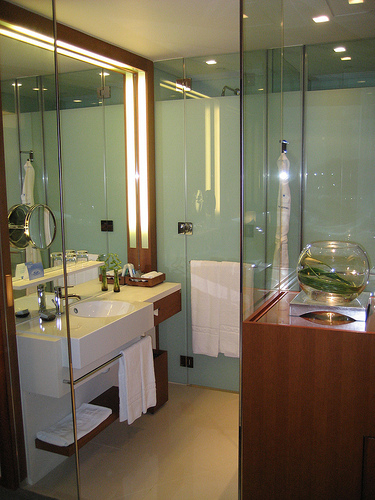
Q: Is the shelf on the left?
A: Yes, the shelf is on the left of the image.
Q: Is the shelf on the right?
A: No, the shelf is on the left of the image.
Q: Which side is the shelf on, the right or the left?
A: The shelf is on the left of the image.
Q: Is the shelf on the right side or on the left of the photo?
A: The shelf is on the left of the image.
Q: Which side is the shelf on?
A: The shelf is on the left of the image.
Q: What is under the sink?
A: The shelf is under the sink.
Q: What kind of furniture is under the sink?
A: The piece of furniture is a shelf.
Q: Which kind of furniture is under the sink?
A: The piece of furniture is a shelf.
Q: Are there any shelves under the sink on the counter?
A: Yes, there is a shelf under the sink.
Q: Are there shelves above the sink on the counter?
A: No, the shelf is under the sink.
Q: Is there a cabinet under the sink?
A: No, there is a shelf under the sink.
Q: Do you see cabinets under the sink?
A: No, there is a shelf under the sink.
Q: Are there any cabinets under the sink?
A: No, there is a shelf under the sink.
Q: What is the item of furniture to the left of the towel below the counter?
A: The piece of furniture is a shelf.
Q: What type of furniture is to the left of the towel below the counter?
A: The piece of furniture is a shelf.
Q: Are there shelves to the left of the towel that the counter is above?
A: Yes, there is a shelf to the left of the towel.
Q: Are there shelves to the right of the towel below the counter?
A: No, the shelf is to the left of the towel.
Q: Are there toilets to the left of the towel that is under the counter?
A: No, there is a shelf to the left of the towel.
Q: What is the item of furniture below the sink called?
A: The piece of furniture is a shelf.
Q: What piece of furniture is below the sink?
A: The piece of furniture is a shelf.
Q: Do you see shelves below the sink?
A: Yes, there is a shelf below the sink.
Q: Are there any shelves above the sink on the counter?
A: No, the shelf is below the sink.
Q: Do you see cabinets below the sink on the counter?
A: No, there is a shelf below the sink.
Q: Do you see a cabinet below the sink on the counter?
A: No, there is a shelf below the sink.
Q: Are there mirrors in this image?
A: Yes, there is a mirror.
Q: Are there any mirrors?
A: Yes, there is a mirror.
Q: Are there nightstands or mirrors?
A: Yes, there is a mirror.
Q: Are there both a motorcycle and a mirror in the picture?
A: No, there is a mirror but no motorcycles.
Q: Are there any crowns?
A: No, there are no crowns.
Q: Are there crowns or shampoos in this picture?
A: No, there are no crowns or shampoos.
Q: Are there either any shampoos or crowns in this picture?
A: No, there are no crowns or shampoos.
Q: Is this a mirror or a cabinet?
A: This is a mirror.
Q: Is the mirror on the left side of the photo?
A: Yes, the mirror is on the left of the image.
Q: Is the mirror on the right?
A: No, the mirror is on the left of the image.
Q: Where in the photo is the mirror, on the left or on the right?
A: The mirror is on the left of the image.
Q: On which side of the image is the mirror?
A: The mirror is on the left of the image.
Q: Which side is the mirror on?
A: The mirror is on the left of the image.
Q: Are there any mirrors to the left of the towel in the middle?
A: Yes, there is a mirror to the left of the towel.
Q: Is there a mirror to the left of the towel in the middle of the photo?
A: Yes, there is a mirror to the left of the towel.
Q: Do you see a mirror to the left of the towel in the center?
A: Yes, there is a mirror to the left of the towel.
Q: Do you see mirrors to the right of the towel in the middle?
A: No, the mirror is to the left of the towel.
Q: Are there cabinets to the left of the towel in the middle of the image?
A: No, there is a mirror to the left of the towel.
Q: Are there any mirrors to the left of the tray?
A: Yes, there is a mirror to the left of the tray.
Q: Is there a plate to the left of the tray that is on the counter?
A: No, there is a mirror to the left of the tray.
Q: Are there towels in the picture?
A: Yes, there is a towel.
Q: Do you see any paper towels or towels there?
A: Yes, there is a towel.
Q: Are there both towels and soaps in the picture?
A: No, there is a towel but no soaps.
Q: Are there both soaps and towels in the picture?
A: No, there is a towel but no soaps.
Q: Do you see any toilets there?
A: No, there are no toilets.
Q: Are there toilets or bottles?
A: No, there are no toilets or bottles.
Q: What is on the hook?
A: The towel is on the hook.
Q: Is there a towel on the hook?
A: Yes, there is a towel on the hook.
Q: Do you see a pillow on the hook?
A: No, there is a towel on the hook.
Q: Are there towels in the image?
A: Yes, there is a towel.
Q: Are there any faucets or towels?
A: Yes, there is a towel.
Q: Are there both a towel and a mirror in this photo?
A: Yes, there are both a towel and a mirror.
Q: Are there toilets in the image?
A: No, there are no toilets.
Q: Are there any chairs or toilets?
A: No, there are no toilets or chairs.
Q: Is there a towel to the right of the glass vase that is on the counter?
A: Yes, there is a towel to the right of the vase.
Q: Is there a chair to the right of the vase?
A: No, there is a towel to the right of the vase.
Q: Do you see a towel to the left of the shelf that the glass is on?
A: No, the towel is to the right of the shelf.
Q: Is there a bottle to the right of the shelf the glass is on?
A: No, there is a towel to the right of the shelf.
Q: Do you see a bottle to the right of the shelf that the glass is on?
A: No, there is a towel to the right of the shelf.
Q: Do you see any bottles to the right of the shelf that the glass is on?
A: No, there is a towel to the right of the shelf.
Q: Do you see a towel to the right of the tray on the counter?
A: Yes, there is a towel to the right of the tray.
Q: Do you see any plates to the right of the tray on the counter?
A: No, there is a towel to the right of the tray.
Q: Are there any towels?
A: Yes, there is a towel.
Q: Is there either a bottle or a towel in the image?
A: Yes, there is a towel.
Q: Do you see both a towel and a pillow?
A: No, there is a towel but no pillows.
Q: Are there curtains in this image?
A: No, there are no curtains.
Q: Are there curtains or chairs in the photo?
A: No, there are no curtains or chairs.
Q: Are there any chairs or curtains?
A: No, there are no curtains or chairs.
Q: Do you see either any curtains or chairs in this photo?
A: No, there are no curtains or chairs.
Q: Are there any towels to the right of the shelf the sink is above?
A: Yes, there is a towel to the right of the shelf.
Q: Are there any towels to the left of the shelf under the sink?
A: No, the towel is to the right of the shelf.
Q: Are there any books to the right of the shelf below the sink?
A: No, there is a towel to the right of the shelf.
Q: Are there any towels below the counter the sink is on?
A: Yes, there is a towel below the counter.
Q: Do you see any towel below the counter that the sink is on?
A: Yes, there is a towel below the counter.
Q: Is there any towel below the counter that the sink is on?
A: Yes, there is a towel below the counter.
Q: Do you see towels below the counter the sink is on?
A: Yes, there is a towel below the counter.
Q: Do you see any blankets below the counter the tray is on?
A: No, there is a towel below the counter.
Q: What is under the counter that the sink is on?
A: The towel is under the counter.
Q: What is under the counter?
A: The towel is under the counter.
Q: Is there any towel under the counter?
A: Yes, there is a towel under the counter.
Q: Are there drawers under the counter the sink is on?
A: No, there is a towel under the counter.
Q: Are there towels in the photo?
A: Yes, there is a towel.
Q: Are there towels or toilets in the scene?
A: Yes, there is a towel.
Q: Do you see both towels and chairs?
A: No, there is a towel but no chairs.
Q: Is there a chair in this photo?
A: No, there are no chairs.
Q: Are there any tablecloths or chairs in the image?
A: No, there are no chairs or tablecloths.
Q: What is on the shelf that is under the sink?
A: The towel is on the shelf.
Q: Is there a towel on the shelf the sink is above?
A: Yes, there is a towel on the shelf.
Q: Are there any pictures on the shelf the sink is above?
A: No, there is a towel on the shelf.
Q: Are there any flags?
A: No, there are no flags.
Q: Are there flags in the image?
A: No, there are no flags.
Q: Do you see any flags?
A: No, there are no flags.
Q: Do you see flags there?
A: No, there are no flags.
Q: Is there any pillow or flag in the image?
A: No, there are no flags or pillows.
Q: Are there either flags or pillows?
A: No, there are no flags or pillows.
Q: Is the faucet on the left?
A: Yes, the faucet is on the left of the image.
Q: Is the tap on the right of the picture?
A: No, the tap is on the left of the image.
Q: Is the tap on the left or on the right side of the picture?
A: The tap is on the left of the image.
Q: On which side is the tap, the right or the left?
A: The tap is on the left of the image.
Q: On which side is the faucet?
A: The faucet is on the left of the image.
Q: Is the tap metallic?
A: Yes, the tap is metallic.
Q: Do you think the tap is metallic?
A: Yes, the tap is metallic.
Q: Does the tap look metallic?
A: Yes, the tap is metallic.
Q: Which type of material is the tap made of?
A: The tap is made of metal.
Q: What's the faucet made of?
A: The tap is made of metal.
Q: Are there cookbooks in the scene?
A: No, there are no cookbooks.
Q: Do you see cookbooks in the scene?
A: No, there are no cookbooks.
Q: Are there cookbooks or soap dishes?
A: No, there are no cookbooks or soap dishes.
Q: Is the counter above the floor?
A: Yes, the counter is above the floor.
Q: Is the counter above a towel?
A: Yes, the counter is above a towel.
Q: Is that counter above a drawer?
A: No, the counter is above a towel.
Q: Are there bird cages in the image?
A: No, there are no bird cages.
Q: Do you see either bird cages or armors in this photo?
A: No, there are no bird cages or armors.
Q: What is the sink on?
A: The sink is on the counter.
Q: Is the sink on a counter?
A: Yes, the sink is on a counter.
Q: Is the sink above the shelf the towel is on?
A: Yes, the sink is above the shelf.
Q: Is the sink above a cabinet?
A: No, the sink is above the shelf.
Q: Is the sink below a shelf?
A: No, the sink is above a shelf.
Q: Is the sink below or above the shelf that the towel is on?
A: The sink is above the shelf.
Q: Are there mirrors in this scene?
A: Yes, there is a mirror.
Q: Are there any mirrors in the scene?
A: Yes, there is a mirror.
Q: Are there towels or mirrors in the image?
A: Yes, there is a mirror.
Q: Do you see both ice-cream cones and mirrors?
A: No, there is a mirror but no ice-cream cones.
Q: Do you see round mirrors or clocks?
A: Yes, there is a round mirror.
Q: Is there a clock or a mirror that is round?
A: Yes, the mirror is round.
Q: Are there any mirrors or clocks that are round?
A: Yes, the mirror is round.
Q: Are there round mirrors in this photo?
A: Yes, there is a round mirror.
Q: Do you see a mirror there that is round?
A: Yes, there is a mirror that is round.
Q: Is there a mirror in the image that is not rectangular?
A: Yes, there is a round mirror.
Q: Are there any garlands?
A: No, there are no garlands.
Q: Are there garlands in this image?
A: No, there are no garlands.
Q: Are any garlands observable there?
A: No, there are no garlands.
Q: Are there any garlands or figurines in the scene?
A: No, there are no garlands or figurines.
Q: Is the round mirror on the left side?
A: Yes, the mirror is on the left of the image.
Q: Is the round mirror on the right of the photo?
A: No, the mirror is on the left of the image.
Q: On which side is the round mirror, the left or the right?
A: The mirror is on the left of the image.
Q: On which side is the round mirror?
A: The mirror is on the left of the image.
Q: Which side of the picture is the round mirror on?
A: The mirror is on the left of the image.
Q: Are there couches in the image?
A: No, there are no couches.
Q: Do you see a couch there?
A: No, there are no couches.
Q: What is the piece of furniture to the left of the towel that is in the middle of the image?
A: The piece of furniture is a shelf.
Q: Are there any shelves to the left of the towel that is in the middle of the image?
A: Yes, there is a shelf to the left of the towel.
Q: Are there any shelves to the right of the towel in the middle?
A: No, the shelf is to the left of the towel.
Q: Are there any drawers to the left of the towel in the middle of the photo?
A: No, there is a shelf to the left of the towel.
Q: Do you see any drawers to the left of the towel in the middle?
A: No, there is a shelf to the left of the towel.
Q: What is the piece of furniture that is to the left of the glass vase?
A: The piece of furniture is a shelf.